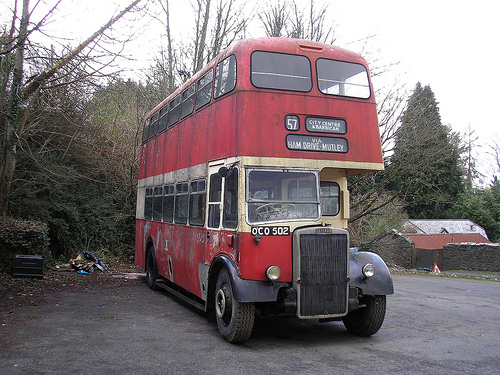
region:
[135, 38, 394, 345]
red, white and blue bus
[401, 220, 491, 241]
white roof in the distance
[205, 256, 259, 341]
right front wheel of the bus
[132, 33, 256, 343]
right side of the bus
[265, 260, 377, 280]
headlights of the bus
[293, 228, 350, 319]
front grill of the bus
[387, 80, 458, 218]
tall tree to the left of the bus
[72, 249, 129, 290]
the pile in dirt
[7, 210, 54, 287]
tree limbs in garbage bin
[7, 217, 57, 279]
garbage bin is gray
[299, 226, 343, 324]
the grill is black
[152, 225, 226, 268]
rust on the bus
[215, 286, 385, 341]
the wheels are black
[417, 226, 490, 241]
the roof is red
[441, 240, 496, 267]
the wall is made of rocks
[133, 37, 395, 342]
the old double decker bus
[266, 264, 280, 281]
the headlight on the old double decker bus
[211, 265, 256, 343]
the font wheel on the old double decker bus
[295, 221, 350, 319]
the grill on the old double decker bus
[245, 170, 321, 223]
the windshield on the old double decker bus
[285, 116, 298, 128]
the number 57 on the old double decker bus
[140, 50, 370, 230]
all the windows on the old double decker bus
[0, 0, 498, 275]
the trees around the old double decker bus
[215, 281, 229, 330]
the rim on the tire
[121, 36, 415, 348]
red and white double decker bus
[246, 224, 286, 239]
black and white license plate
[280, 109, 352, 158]
white text on black background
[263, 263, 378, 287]
headlights on the bus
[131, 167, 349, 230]
white section of the bus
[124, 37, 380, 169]
second deck of the bus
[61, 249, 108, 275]
debris pile next to bus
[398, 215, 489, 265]
houses behind stone wall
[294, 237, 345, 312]
front grill on bus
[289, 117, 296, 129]
the numbers are white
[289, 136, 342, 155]
the letters are white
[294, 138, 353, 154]
letters on the sign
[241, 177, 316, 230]
license plate under window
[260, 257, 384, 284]
the headlights on bus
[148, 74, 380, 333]
the bus is double decker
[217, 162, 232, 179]
mirror on the bus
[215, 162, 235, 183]
the mirror on bus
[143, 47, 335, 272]
the bus is red